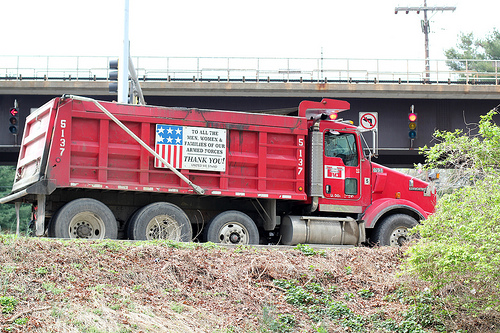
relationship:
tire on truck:
[50, 197, 122, 245] [1, 90, 447, 247]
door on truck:
[320, 126, 366, 202] [1, 90, 447, 247]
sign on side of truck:
[148, 122, 232, 174] [1, 90, 447, 247]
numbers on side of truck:
[292, 137, 308, 180] [1, 90, 447, 247]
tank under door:
[276, 213, 363, 248] [320, 126, 366, 202]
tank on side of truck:
[276, 213, 363, 248] [1, 90, 447, 247]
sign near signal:
[355, 110, 380, 133] [404, 112, 420, 143]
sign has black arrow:
[355, 110, 380, 133] [361, 115, 372, 127]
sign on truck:
[148, 122, 232, 174] [1, 90, 447, 247]